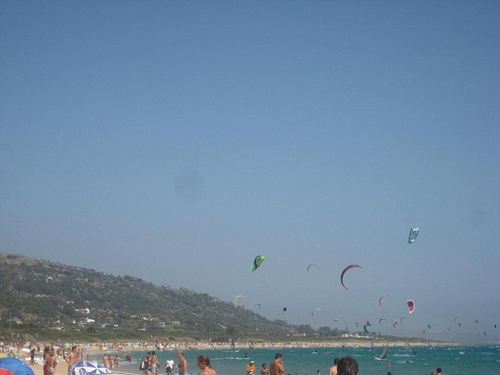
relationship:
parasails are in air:
[233, 225, 498, 348] [4, 3, 498, 345]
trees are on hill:
[0, 254, 428, 342] [0, 254, 421, 341]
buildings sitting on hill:
[46, 301, 153, 334] [0, 254, 421, 341]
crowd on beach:
[1, 341, 449, 374] [2, 342, 460, 374]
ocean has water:
[88, 345, 500, 374] [84, 347, 500, 373]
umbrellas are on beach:
[0, 355, 111, 374] [2, 342, 460, 374]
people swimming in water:
[105, 348, 449, 373] [84, 347, 500, 373]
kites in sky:
[233, 225, 500, 338] [0, 0, 499, 347]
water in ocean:
[84, 347, 500, 373] [88, 345, 500, 374]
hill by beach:
[0, 254, 421, 341] [2, 342, 460, 374]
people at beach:
[105, 348, 449, 373] [2, 342, 460, 374]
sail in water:
[377, 340, 391, 362] [84, 347, 500, 373]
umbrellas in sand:
[0, 355, 111, 374] [2, 340, 454, 373]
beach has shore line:
[2, 342, 460, 374] [0, 341, 456, 374]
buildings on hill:
[46, 301, 153, 334] [0, 254, 421, 341]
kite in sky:
[340, 264, 363, 291] [0, 0, 499, 347]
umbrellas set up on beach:
[0, 355, 111, 374] [2, 342, 460, 374]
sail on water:
[377, 340, 391, 362] [84, 347, 500, 373]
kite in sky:
[406, 301, 417, 317] [0, 0, 499, 347]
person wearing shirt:
[166, 357, 177, 374] [166, 359, 175, 370]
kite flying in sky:
[340, 261, 363, 289] [0, 0, 499, 347]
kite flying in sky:
[408, 227, 421, 247] [0, 0, 499, 347]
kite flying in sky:
[307, 264, 322, 274] [0, 0, 499, 347]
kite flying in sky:
[406, 301, 417, 317] [0, 0, 499, 347]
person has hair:
[336, 358, 358, 375] [339, 358, 361, 374]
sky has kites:
[0, 0, 499, 347] [233, 225, 500, 338]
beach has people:
[2, 342, 460, 374] [0, 340, 443, 373]